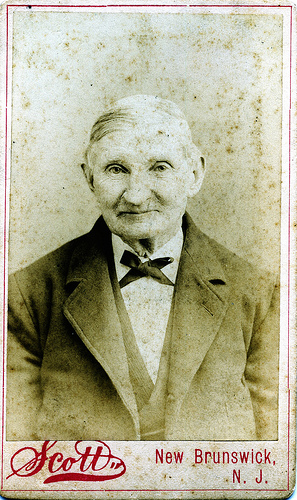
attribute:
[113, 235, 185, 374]
shirt — white 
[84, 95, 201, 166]
grey hair — gray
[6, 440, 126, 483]
words — red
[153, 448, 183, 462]
words — red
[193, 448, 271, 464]
words — red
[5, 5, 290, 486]
border — red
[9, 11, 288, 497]
photo — old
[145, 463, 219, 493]
rust spots — rust 